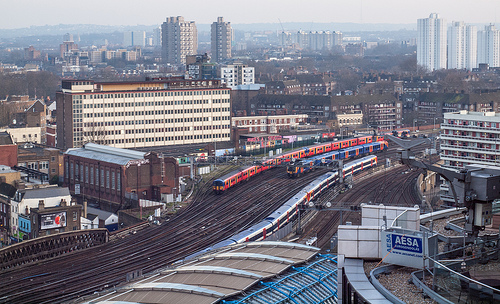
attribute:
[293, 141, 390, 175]
train — moving, blue, red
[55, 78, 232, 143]
large building — brown, white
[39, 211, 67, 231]
adverstisment sign — billboard, red, blue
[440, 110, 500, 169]
large building — apartments, white apartments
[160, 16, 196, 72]
high rise building — brown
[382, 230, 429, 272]
aesa sign — a billboard, advertisment, an ad, white, blue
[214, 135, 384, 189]
red train — long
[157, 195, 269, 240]
railroad tracks — empty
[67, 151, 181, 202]
building — factory, brown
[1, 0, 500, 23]
sky — grey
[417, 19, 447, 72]
building — in a cluster, tall, aparments, white, gray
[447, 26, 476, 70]
building — white